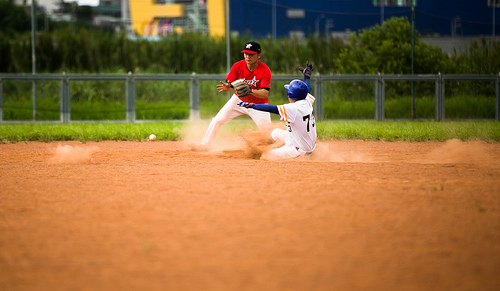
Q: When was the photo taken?
A: Daytime.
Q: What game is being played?
A: Baseball.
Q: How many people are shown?
A: Two.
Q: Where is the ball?
A: Air.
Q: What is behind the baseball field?
A: Fence.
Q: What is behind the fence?
A: Trees.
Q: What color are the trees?
A: Green.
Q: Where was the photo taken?
A: At a ball park.